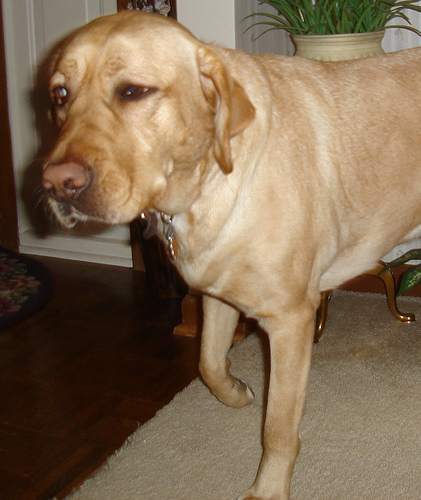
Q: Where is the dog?
A: In the living room.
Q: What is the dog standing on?
A: The rug.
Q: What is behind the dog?
A: A plant in a vase?.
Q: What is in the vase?
A: A plant.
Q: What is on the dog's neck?
A: A collar.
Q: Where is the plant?
A: In the corner.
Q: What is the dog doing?
A: Standing.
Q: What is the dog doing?
A: Staring at someone.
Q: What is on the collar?
A: A tag.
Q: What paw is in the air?
A: Right.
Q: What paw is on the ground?
A: Left.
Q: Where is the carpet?
A: Under dog.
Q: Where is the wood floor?
A: Next to carpet.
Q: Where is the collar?
A: Around dog's neck.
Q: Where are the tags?
A: On Collar.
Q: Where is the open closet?
A: Behind dog's head.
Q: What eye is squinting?
A: Left.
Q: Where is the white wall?
A: Behind the dog.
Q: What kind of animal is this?
A: Dog.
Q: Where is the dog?
A: Inside the house.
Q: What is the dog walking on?
A: Rug.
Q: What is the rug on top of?
A: Hardwood floors.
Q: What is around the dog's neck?
A: Dog collar.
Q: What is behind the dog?
A: Potted plant.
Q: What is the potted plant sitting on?
A: Wooden table.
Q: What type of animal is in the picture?
A: Dog.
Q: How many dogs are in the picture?
A: One.